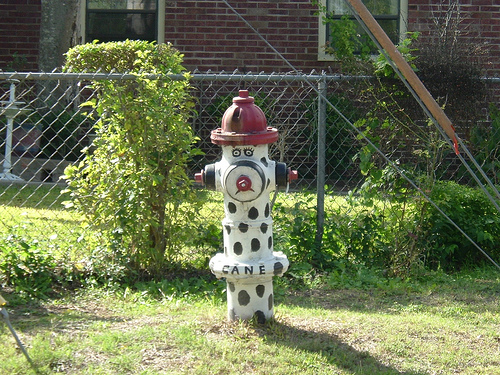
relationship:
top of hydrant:
[212, 91, 270, 148] [195, 79, 294, 336]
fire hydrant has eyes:
[195, 89, 298, 325] [225, 141, 263, 160]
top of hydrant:
[211, 91, 280, 145] [195, 79, 294, 336]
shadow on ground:
[308, 325, 369, 371] [0, 276, 498, 368]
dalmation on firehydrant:
[233, 239, 246, 257] [188, 74, 304, 333]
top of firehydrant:
[211, 91, 280, 145] [188, 74, 304, 333]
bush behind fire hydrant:
[49, 30, 207, 291] [198, 79, 294, 346]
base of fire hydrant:
[206, 289, 288, 340] [198, 79, 294, 346]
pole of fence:
[303, 96, 346, 286] [0, 69, 498, 279]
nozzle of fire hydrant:
[272, 156, 310, 190] [188, 87, 307, 332]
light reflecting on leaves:
[19, 213, 94, 268] [10, 231, 97, 268]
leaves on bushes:
[10, 231, 97, 268] [4, 211, 111, 315]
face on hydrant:
[226, 140, 269, 210] [185, 85, 312, 336]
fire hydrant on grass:
[195, 89, 298, 325] [1, 182, 493, 372]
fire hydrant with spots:
[195, 89, 298, 325] [221, 204, 278, 326]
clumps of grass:
[90, 332, 175, 372] [10, 273, 499, 373]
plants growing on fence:
[280, 196, 420, 290] [0, 69, 498, 279]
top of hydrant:
[211, 91, 280, 145] [200, 85, 310, 333]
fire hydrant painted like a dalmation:
[195, 89, 298, 325] [207, 145, 287, 332]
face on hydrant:
[226, 140, 269, 210] [192, 88, 305, 331]